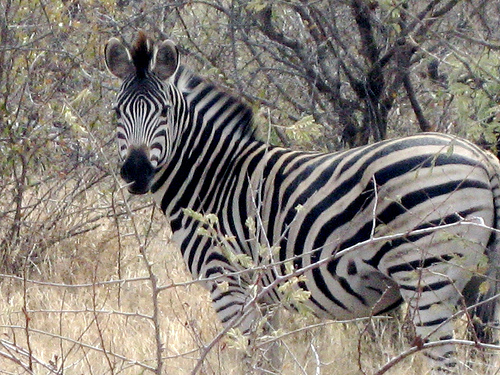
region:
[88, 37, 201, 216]
face of black and white zebra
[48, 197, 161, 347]
thorny leaf-less branches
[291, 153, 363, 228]
black and white stripes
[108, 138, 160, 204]
a black zebra muzzle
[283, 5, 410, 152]
trunk of a large tree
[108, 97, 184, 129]
two zebra eyes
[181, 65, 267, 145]
striped mane of a zebra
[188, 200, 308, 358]
thorny branches with leaves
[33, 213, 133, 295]
brown grass under a bush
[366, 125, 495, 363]
zebra's rump and back legs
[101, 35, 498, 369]
black and white striped zebra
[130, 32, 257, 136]
black and white striped zebra mane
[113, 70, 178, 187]
black and white striped zebra head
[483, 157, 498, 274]
black and white striped zebra tail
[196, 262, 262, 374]
black and white striped zebra leg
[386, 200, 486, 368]
black and white striped zebra leg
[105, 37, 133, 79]
large white and black zebra ear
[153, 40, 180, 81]
large white and black zebra ear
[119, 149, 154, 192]
black snout of zebra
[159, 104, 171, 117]
black eye of zebra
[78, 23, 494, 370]
zebra facing forward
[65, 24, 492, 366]
animal with black and white stripes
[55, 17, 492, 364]
striped animal looking toward the front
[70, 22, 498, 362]
horse-like animal with black nose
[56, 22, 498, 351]
animals with black stripes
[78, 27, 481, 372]
animal with black stripes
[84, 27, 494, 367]
zebra with black mane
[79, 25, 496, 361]
zebra standing by itself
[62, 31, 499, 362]
zebra in the wilderness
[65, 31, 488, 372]
zebra out in the woods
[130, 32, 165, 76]
spiny tuft of hair on zebra head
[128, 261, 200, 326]
dry twig attached to bush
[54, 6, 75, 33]
green leaves on tree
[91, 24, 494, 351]
black and white zebra looking at camera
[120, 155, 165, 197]
dried straw being eaten by zebra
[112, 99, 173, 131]
two brown eyes on zebra's head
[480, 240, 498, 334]
fluffy tail of a zebra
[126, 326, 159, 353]
yellow dried grass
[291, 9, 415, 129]
brown bare tree behind zebra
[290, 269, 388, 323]
black and white pot belly of zebra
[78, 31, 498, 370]
the zebra has black, white, and brown stripes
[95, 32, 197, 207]
the zebra has a black nose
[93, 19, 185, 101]
the zebra has a patch of brown hair on its head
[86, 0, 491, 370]
the zebra is standing in front of a tree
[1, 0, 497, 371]
bare tree branches surround the zebra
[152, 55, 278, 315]
the stripes on the zebra's neck are vertical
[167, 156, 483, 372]
the stripes on the zebra's legs are horizontal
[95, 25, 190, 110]
the zebra has black ears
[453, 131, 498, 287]
the zebra has a tail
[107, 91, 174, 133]
the zebra's eye are far apart